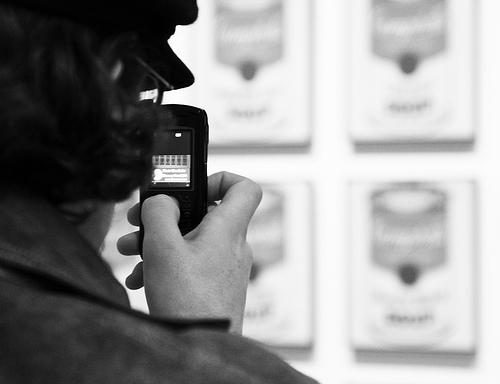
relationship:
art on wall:
[203, 1, 482, 369] [183, 0, 499, 376]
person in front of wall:
[0, 0, 325, 383] [183, 0, 499, 376]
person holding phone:
[0, 0, 325, 383] [138, 97, 205, 264]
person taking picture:
[0, 0, 325, 383] [148, 131, 193, 188]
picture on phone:
[148, 131, 193, 188] [138, 97, 205, 264]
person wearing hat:
[0, 0, 325, 383] [1, 0, 202, 95]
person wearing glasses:
[0, 0, 325, 383] [94, 41, 172, 116]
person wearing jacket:
[0, 0, 325, 383] [3, 182, 321, 384]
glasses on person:
[94, 41, 172, 116] [0, 0, 325, 383]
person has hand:
[0, 0, 325, 383] [138, 170, 260, 338]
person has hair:
[0, 0, 325, 383] [3, 11, 171, 200]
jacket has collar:
[3, 182, 321, 384] [1, 178, 140, 317]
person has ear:
[0, 0, 325, 383] [99, 60, 151, 123]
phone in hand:
[138, 97, 205, 264] [138, 170, 260, 338]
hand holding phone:
[138, 170, 260, 338] [138, 97, 205, 264]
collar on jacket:
[1, 178, 140, 317] [3, 182, 321, 384]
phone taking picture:
[138, 97, 205, 264] [148, 131, 193, 188]